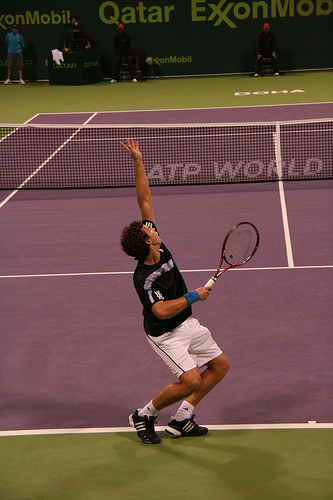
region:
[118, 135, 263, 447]
A tennis player preparing to hit a ball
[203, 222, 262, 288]
a red and black tennis racket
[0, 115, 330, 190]
A tennis net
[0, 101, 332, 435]
a purple tennis court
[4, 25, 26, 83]
a man in a blue shirt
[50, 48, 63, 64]
a white towel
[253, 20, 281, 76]
a person dressed in black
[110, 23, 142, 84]
a person dressed in black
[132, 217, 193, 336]
A black t-shirt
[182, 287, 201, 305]
a blue wristband on a player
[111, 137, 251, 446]
A tennis player serving the tennis ball.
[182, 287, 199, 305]
A blue sweatband.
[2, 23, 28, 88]
A tennis ball assistant.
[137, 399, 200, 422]
A pair of Adidas socks.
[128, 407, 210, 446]
A pair of Adidas tennis shoes.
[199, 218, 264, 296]
A red tennis racket.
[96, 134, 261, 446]
A tennis player throwing the ball up to serve.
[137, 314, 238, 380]
A pair of white tennis shorts.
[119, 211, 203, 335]
A black tennis shirt.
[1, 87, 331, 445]
A purple and green tennis court.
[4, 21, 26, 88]
man on sideline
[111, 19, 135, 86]
man on sideline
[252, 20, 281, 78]
man on sideline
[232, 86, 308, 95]
sign on tennis court floor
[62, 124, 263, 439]
man playing tennis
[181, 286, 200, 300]
wrist band on man's arm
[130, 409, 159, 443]
shoe on man's foot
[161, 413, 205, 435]
shoe on man's arm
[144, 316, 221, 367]
shorts on man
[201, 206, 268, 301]
racquet in man's hand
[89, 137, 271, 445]
man wearing black shirt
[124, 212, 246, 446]
man wearing white shorts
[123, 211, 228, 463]
man wearing white socks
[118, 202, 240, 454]
man wearing black shoes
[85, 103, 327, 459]
man holding a racket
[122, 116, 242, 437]
man hitting a ball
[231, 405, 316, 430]
line on a tennis court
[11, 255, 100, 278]
line on a tennis court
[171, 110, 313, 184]
net on a tennis court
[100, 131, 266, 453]
The man is holding a tennis racket.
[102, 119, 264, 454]
The man's left arm is raised.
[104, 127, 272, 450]
The man's knees are bent.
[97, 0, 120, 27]
The lettering is light green.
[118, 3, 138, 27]
The lettering is light green.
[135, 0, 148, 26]
The lettering is light green.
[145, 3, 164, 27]
The lettering is light green.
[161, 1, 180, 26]
The lettering is light green.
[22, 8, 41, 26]
The lettering is light green.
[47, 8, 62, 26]
The lettering is light green.